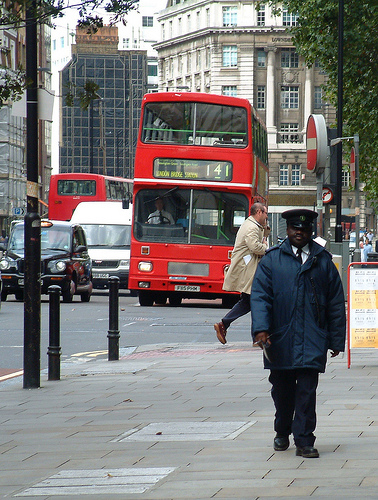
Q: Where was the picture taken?
A: In a city.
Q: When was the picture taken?
A: Daytime.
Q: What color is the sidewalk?
A: Gray.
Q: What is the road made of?
A: Asphalt.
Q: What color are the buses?
A: Red.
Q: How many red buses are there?
A: Two.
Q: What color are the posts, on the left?
A: Black.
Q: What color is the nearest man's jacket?
A: Blue.